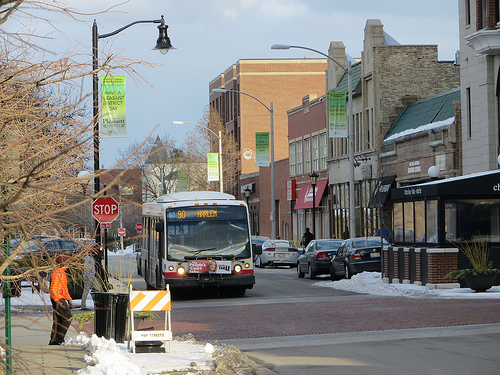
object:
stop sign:
[117, 228, 125, 236]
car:
[253, 239, 298, 268]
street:
[238, 254, 372, 374]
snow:
[311, 270, 439, 298]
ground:
[207, 294, 500, 375]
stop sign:
[90, 191, 120, 223]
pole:
[104, 229, 108, 292]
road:
[177, 289, 496, 374]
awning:
[294, 179, 329, 210]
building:
[285, 93, 330, 249]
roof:
[381, 89, 460, 146]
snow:
[382, 116, 459, 142]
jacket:
[50, 267, 73, 302]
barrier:
[124, 283, 173, 353]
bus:
[141, 191, 256, 296]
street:
[178, 294, 498, 372]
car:
[329, 236, 389, 279]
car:
[296, 239, 345, 279]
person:
[48, 255, 74, 345]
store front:
[284, 93, 328, 250]